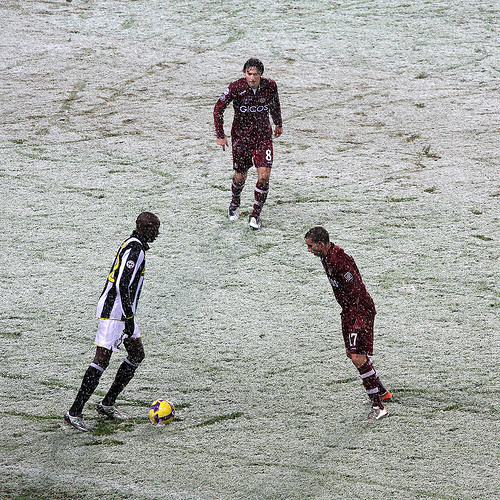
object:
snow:
[1, 1, 500, 500]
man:
[304, 226, 392, 422]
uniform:
[321, 242, 377, 355]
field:
[0, 0, 500, 500]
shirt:
[213, 77, 283, 142]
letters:
[240, 105, 269, 113]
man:
[78, 172, 161, 434]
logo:
[224, 88, 230, 96]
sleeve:
[213, 79, 240, 139]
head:
[243, 58, 264, 87]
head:
[136, 212, 160, 243]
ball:
[149, 399, 176, 425]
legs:
[350, 317, 385, 409]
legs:
[253, 146, 272, 215]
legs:
[76, 319, 115, 411]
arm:
[333, 251, 360, 317]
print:
[126, 260, 135, 269]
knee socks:
[69, 363, 104, 417]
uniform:
[94, 230, 146, 353]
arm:
[115, 243, 143, 320]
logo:
[344, 271, 354, 282]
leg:
[231, 135, 248, 206]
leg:
[253, 136, 274, 217]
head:
[305, 226, 330, 257]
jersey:
[96, 236, 147, 321]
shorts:
[94, 318, 141, 353]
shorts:
[231, 129, 273, 173]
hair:
[243, 58, 264, 76]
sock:
[357, 360, 379, 401]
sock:
[348, 308, 376, 356]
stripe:
[360, 369, 375, 380]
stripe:
[366, 387, 379, 395]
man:
[213, 57, 283, 230]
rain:
[1, 6, 488, 493]